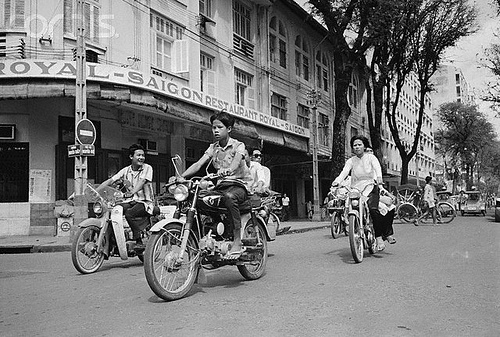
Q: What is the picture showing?
A: It is showing a street.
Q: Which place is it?
A: It is a street.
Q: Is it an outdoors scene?
A: Yes, it is outdoors.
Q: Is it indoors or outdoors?
A: It is outdoors.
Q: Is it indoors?
A: No, it is outdoors.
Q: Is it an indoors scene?
A: No, it is outdoors.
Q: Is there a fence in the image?
A: No, there are no fences.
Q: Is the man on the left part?
A: Yes, the man is on the left of the image.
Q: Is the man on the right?
A: No, the man is on the left of the image.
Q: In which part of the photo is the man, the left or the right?
A: The man is on the left of the image.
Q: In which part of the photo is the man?
A: The man is on the left of the image.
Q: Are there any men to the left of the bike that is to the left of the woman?
A: Yes, there is a man to the left of the bike.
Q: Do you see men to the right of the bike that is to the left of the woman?
A: No, the man is to the left of the bike.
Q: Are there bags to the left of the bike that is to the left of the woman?
A: No, there is a man to the left of the bike.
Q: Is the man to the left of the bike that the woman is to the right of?
A: Yes, the man is to the left of the bike.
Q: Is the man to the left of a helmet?
A: No, the man is to the left of the bike.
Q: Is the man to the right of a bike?
A: No, the man is to the left of a bike.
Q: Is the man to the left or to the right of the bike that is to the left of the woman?
A: The man is to the left of the bike.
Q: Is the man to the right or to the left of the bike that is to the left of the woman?
A: The man is to the left of the bike.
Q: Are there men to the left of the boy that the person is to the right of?
A: Yes, there is a man to the left of the boy.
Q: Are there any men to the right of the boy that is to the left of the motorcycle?
A: No, the man is to the left of the boy.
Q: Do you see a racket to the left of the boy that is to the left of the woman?
A: No, there is a man to the left of the boy.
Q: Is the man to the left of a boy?
A: Yes, the man is to the left of a boy.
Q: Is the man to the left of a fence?
A: No, the man is to the left of a boy.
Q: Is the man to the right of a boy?
A: No, the man is to the left of a boy.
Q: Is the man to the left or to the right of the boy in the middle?
A: The man is to the left of the boy.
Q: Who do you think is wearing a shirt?
A: The man is wearing a shirt.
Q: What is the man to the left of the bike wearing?
A: The man is wearing a shirt.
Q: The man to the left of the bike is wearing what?
A: The man is wearing a shirt.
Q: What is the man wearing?
A: The man is wearing a shirt.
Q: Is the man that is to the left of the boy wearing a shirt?
A: Yes, the man is wearing a shirt.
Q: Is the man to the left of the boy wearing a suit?
A: No, the man is wearing a shirt.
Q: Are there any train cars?
A: No, there are no train cars.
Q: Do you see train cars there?
A: No, there are no train cars.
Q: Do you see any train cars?
A: No, there are no train cars.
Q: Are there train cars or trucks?
A: No, there are no train cars or trucks.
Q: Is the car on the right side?
A: Yes, the car is on the right of the image.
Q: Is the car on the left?
A: No, the car is on the right of the image.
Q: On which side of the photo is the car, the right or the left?
A: The car is on the right of the image.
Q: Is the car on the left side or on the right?
A: The car is on the right of the image.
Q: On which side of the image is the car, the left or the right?
A: The car is on the right of the image.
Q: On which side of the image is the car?
A: The car is on the right of the image.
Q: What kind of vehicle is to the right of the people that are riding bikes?
A: The vehicle is a car.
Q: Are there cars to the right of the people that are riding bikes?
A: Yes, there is a car to the right of the people.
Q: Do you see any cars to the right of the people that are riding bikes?
A: Yes, there is a car to the right of the people.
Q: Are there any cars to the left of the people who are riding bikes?
A: No, the car is to the right of the people.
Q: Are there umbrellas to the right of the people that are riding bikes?
A: No, there is a car to the right of the people.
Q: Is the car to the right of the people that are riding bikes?
A: Yes, the car is to the right of the people.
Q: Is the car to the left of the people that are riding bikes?
A: No, the car is to the right of the people.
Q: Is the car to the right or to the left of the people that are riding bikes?
A: The car is to the right of the people.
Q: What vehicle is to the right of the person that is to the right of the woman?
A: The vehicle is a car.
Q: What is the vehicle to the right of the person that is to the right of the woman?
A: The vehicle is a car.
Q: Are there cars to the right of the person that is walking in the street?
A: Yes, there is a car to the right of the person.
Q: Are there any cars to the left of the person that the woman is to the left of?
A: No, the car is to the right of the person.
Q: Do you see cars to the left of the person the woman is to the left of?
A: No, the car is to the right of the person.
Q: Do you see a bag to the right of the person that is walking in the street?
A: No, there is a car to the right of the person.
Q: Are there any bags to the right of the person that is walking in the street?
A: No, there is a car to the right of the person.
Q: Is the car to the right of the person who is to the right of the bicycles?
A: Yes, the car is to the right of the person.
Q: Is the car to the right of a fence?
A: No, the car is to the right of the person.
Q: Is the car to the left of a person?
A: No, the car is to the right of a person.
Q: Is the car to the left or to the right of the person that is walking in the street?
A: The car is to the right of the person.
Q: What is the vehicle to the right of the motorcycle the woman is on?
A: The vehicle is a car.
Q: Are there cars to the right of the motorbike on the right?
A: Yes, there is a car to the right of the motorcycle.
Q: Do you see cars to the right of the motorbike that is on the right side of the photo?
A: Yes, there is a car to the right of the motorcycle.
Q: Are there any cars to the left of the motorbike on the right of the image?
A: No, the car is to the right of the motorbike.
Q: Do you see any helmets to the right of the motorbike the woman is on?
A: No, there is a car to the right of the motorbike.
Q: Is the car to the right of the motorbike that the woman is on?
A: Yes, the car is to the right of the motorbike.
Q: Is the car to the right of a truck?
A: No, the car is to the right of the motorbike.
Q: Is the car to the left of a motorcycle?
A: No, the car is to the right of a motorcycle.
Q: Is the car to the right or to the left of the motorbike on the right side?
A: The car is to the right of the motorbike.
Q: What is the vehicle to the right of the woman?
A: The vehicle is a car.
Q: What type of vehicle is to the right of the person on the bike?
A: The vehicle is a car.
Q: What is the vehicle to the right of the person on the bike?
A: The vehicle is a car.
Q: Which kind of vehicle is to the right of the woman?
A: The vehicle is a car.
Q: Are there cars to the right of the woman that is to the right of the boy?
A: Yes, there is a car to the right of the woman.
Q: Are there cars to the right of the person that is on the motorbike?
A: Yes, there is a car to the right of the woman.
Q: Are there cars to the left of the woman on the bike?
A: No, the car is to the right of the woman.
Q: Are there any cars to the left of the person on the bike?
A: No, the car is to the right of the woman.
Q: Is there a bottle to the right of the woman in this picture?
A: No, there is a car to the right of the woman.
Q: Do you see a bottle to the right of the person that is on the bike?
A: No, there is a car to the right of the woman.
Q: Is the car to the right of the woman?
A: Yes, the car is to the right of the woman.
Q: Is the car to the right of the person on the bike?
A: Yes, the car is to the right of the woman.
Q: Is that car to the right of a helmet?
A: No, the car is to the right of the woman.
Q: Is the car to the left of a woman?
A: No, the car is to the right of a woman.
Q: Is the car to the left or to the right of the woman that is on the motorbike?
A: The car is to the right of the woman.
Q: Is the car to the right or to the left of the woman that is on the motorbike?
A: The car is to the right of the woman.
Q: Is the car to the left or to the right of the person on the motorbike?
A: The car is to the right of the woman.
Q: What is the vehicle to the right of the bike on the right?
A: The vehicle is a car.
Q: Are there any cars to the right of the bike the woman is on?
A: Yes, there is a car to the right of the bike.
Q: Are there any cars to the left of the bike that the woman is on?
A: No, the car is to the right of the bike.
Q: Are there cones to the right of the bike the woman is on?
A: No, there is a car to the right of the bike.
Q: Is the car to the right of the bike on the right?
A: Yes, the car is to the right of the bike.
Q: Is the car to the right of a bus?
A: No, the car is to the right of the bike.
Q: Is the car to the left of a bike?
A: No, the car is to the right of a bike.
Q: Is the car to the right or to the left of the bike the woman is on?
A: The car is to the right of the bike.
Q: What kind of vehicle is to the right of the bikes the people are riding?
A: The vehicle is a car.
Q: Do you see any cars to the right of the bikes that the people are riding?
A: Yes, there is a car to the right of the bikes.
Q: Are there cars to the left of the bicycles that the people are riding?
A: No, the car is to the right of the bikes.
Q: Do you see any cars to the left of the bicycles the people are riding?
A: No, the car is to the right of the bikes.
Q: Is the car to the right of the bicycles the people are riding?
A: Yes, the car is to the right of the bikes.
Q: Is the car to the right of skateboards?
A: No, the car is to the right of the bikes.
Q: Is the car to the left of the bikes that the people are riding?
A: No, the car is to the right of the bikes.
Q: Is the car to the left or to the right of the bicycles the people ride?
A: The car is to the right of the bikes.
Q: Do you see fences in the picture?
A: No, there are no fences.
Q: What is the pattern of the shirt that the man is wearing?
A: The shirt is striped.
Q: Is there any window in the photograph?
A: Yes, there is a window.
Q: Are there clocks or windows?
A: Yes, there is a window.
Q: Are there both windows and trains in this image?
A: No, there is a window but no trains.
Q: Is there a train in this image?
A: No, there are no trains.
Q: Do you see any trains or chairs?
A: No, there are no trains or chairs.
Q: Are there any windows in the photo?
A: Yes, there is a window.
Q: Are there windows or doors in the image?
A: Yes, there is a window.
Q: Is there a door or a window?
A: Yes, there is a window.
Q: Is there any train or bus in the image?
A: No, there are no buses or trains.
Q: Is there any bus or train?
A: No, there are no buses or trains.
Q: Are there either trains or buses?
A: No, there are no buses or trains.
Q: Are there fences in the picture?
A: No, there are no fences.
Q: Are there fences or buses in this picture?
A: No, there are no fences or buses.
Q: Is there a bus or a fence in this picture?
A: No, there are no fences or buses.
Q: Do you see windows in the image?
A: Yes, there is a window.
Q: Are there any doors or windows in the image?
A: Yes, there is a window.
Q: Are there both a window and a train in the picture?
A: No, there is a window but no trains.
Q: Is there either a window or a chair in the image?
A: Yes, there is a window.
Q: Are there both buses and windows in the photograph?
A: No, there is a window but no buses.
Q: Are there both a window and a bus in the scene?
A: No, there is a window but no buses.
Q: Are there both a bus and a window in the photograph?
A: No, there is a window but no buses.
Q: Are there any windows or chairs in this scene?
A: Yes, there is a window.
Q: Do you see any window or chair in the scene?
A: Yes, there is a window.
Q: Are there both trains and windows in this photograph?
A: No, there is a window but no trains.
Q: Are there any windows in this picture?
A: Yes, there is a window.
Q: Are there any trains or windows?
A: Yes, there is a window.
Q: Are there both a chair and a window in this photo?
A: No, there is a window but no chairs.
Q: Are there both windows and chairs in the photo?
A: No, there is a window but no chairs.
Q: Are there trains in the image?
A: No, there are no trains.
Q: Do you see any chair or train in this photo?
A: No, there are no trains or chairs.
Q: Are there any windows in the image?
A: Yes, there are windows.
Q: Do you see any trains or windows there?
A: Yes, there are windows.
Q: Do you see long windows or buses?
A: Yes, there are long windows.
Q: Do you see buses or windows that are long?
A: Yes, the windows are long.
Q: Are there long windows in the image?
A: Yes, there are long windows.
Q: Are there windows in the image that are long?
A: Yes, there are windows that are long.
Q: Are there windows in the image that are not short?
A: Yes, there are long windows.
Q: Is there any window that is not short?
A: Yes, there are long windows.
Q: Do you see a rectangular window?
A: Yes, there are rectangular windows.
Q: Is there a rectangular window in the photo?
A: Yes, there are rectangular windows.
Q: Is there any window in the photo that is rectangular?
A: Yes, there are windows that are rectangular.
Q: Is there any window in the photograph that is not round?
A: Yes, there are rectangular windows.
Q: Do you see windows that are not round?
A: Yes, there are rectangular windows.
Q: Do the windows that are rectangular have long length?
A: Yes, the windows are long.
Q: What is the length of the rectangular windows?
A: The windows are long.